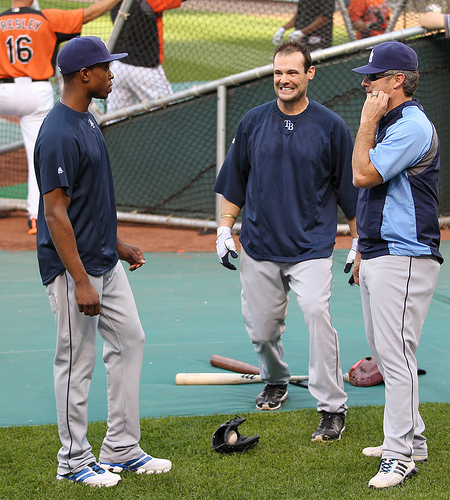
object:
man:
[214, 41, 363, 444]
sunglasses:
[356, 68, 393, 91]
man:
[344, 38, 450, 490]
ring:
[370, 90, 383, 103]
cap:
[349, 38, 418, 76]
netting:
[1, 3, 450, 228]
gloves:
[209, 229, 242, 273]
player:
[32, 35, 171, 493]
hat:
[56, 32, 133, 76]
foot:
[255, 374, 291, 413]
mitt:
[214, 419, 258, 455]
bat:
[170, 366, 346, 385]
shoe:
[311, 409, 348, 443]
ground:
[0, 239, 450, 499]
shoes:
[371, 453, 414, 488]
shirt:
[0, 5, 84, 86]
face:
[271, 50, 307, 100]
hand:
[215, 229, 241, 275]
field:
[1, 400, 450, 499]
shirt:
[212, 105, 364, 270]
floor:
[0, 245, 450, 425]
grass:
[4, 405, 450, 499]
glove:
[347, 345, 394, 387]